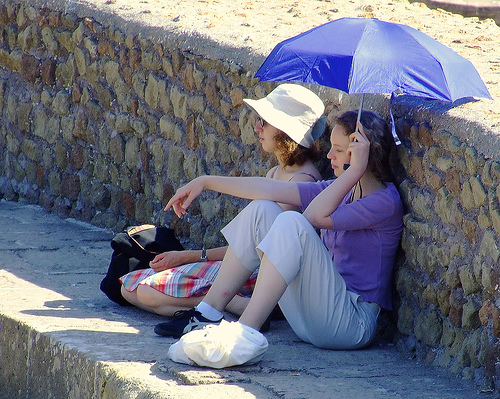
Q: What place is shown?
A: It is a sidewalk.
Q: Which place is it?
A: It is a sidewalk.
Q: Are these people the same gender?
A: Yes, all the people are female.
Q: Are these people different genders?
A: No, all the people are female.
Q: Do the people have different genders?
A: No, all the people are female.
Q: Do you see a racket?
A: No, there are no rackets.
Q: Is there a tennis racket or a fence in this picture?
A: No, there are no rackets or fences.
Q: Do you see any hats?
A: Yes, there is a hat.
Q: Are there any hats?
A: Yes, there is a hat.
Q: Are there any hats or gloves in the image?
A: Yes, there is a hat.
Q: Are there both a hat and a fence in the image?
A: No, there is a hat but no fences.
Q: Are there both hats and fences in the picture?
A: No, there is a hat but no fences.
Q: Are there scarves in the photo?
A: No, there are no scarves.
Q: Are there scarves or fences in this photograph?
A: No, there are no scarves or fences.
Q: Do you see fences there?
A: No, there are no fences.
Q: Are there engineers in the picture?
A: No, there are no engineers.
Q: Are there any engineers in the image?
A: No, there are no engineers.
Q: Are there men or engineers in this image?
A: No, there are no engineers or men.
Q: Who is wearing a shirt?
A: The girl is wearing a shirt.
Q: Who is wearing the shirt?
A: The girl is wearing a shirt.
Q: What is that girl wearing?
A: The girl is wearing a shirt.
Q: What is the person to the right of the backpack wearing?
A: The girl is wearing a shirt.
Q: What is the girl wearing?
A: The girl is wearing a shirt.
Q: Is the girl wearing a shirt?
A: Yes, the girl is wearing a shirt.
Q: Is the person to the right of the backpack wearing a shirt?
A: Yes, the girl is wearing a shirt.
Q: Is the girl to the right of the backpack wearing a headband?
A: No, the girl is wearing a shirt.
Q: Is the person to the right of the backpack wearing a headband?
A: No, the girl is wearing a shirt.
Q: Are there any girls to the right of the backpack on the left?
A: Yes, there is a girl to the right of the backpack.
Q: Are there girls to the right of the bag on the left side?
A: Yes, there is a girl to the right of the backpack.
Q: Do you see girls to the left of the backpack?
A: No, the girl is to the right of the backpack.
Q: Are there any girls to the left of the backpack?
A: No, the girl is to the right of the backpack.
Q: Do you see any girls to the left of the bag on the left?
A: No, the girl is to the right of the backpack.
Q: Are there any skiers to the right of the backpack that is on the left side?
A: No, there is a girl to the right of the backpack.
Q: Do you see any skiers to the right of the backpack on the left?
A: No, there is a girl to the right of the backpack.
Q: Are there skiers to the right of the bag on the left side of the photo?
A: No, there is a girl to the right of the backpack.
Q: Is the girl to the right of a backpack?
A: Yes, the girl is to the right of a backpack.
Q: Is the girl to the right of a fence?
A: No, the girl is to the right of a backpack.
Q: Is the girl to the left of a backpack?
A: No, the girl is to the right of a backpack.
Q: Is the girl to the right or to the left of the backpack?
A: The girl is to the right of the backpack.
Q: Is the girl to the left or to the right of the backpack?
A: The girl is to the right of the backpack.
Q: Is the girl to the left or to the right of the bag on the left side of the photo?
A: The girl is to the right of the backpack.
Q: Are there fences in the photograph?
A: No, there are no fences.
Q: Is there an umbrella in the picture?
A: Yes, there is an umbrella.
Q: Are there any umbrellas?
A: Yes, there is an umbrella.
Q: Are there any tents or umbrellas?
A: Yes, there is an umbrella.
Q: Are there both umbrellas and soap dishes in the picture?
A: No, there is an umbrella but no soap dishes.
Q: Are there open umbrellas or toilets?
A: Yes, there is an open umbrella.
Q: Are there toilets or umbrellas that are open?
A: Yes, the umbrella is open.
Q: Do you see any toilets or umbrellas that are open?
A: Yes, the umbrella is open.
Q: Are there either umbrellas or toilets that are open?
A: Yes, the umbrella is open.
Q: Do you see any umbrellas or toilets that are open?
A: Yes, the umbrella is open.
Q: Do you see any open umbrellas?
A: Yes, there is an open umbrella.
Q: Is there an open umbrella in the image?
A: Yes, there is an open umbrella.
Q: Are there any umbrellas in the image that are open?
A: Yes, there is an umbrella that is open.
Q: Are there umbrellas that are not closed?
A: Yes, there is a open umbrella.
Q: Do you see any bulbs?
A: No, there are no bulbs.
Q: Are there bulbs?
A: No, there are no bulbs.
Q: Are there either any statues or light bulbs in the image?
A: No, there are no light bulbs or statues.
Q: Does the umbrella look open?
A: Yes, the umbrella is open.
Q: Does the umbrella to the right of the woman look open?
A: Yes, the umbrella is open.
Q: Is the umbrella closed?
A: No, the umbrella is open.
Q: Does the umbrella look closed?
A: No, the umbrella is open.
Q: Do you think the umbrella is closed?
A: No, the umbrella is open.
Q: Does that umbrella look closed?
A: No, the umbrella is open.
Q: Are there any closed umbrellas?
A: No, there is an umbrella but it is open.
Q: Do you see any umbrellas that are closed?
A: No, there is an umbrella but it is open.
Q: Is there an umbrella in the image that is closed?
A: No, there is an umbrella but it is open.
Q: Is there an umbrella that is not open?
A: No, there is an umbrella but it is open.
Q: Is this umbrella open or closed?
A: The umbrella is open.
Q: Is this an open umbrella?
A: Yes, this is an open umbrella.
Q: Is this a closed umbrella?
A: No, this is an open umbrella.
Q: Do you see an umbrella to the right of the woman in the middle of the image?
A: Yes, there is an umbrella to the right of the woman.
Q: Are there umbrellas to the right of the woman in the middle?
A: Yes, there is an umbrella to the right of the woman.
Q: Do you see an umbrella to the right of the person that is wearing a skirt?
A: Yes, there is an umbrella to the right of the woman.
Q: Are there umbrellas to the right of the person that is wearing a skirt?
A: Yes, there is an umbrella to the right of the woman.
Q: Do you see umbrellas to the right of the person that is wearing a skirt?
A: Yes, there is an umbrella to the right of the woman.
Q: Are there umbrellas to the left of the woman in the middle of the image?
A: No, the umbrella is to the right of the woman.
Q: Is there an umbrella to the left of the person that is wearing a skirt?
A: No, the umbrella is to the right of the woman.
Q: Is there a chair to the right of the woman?
A: No, there is an umbrella to the right of the woman.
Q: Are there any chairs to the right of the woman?
A: No, there is an umbrella to the right of the woman.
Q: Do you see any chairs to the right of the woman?
A: No, there is an umbrella to the right of the woman.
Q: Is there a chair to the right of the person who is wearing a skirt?
A: No, there is an umbrella to the right of the woman.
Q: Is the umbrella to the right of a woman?
A: Yes, the umbrella is to the right of a woman.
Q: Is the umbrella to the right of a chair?
A: No, the umbrella is to the right of a woman.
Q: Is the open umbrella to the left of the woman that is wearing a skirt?
A: No, the umbrella is to the right of the woman.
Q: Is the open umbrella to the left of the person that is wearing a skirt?
A: No, the umbrella is to the right of the woman.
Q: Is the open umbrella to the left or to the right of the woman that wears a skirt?
A: The umbrella is to the right of the woman.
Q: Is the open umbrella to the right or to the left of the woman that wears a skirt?
A: The umbrella is to the right of the woman.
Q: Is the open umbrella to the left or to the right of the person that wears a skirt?
A: The umbrella is to the right of the woman.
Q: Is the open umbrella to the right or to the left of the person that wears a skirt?
A: The umbrella is to the right of the woman.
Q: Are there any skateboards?
A: No, there are no skateboards.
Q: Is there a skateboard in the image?
A: No, there are no skateboards.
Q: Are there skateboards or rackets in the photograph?
A: No, there are no skateboards or rackets.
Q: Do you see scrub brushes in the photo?
A: No, there are no scrub brushes.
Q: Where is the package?
A: The package is on the sidewalk.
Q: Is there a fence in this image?
A: No, there are no fences.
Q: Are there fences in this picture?
A: No, there are no fences.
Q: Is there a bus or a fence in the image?
A: No, there are no fences or buses.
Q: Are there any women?
A: Yes, there is a woman.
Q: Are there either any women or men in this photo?
A: Yes, there is a woman.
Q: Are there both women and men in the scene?
A: No, there is a woman but no men.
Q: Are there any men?
A: No, there are no men.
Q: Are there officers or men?
A: No, there are no men or officers.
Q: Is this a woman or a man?
A: This is a woman.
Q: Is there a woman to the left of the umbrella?
A: Yes, there is a woman to the left of the umbrella.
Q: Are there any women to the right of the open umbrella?
A: No, the woman is to the left of the umbrella.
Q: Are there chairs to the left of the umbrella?
A: No, there is a woman to the left of the umbrella.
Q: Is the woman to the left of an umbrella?
A: Yes, the woman is to the left of an umbrella.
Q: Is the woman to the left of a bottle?
A: No, the woman is to the left of an umbrella.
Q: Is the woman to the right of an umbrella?
A: No, the woman is to the left of an umbrella.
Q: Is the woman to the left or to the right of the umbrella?
A: The woman is to the left of the umbrella.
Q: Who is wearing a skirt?
A: The woman is wearing a skirt.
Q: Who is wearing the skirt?
A: The woman is wearing a skirt.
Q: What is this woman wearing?
A: The woman is wearing a skirt.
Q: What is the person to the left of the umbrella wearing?
A: The woman is wearing a skirt.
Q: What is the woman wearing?
A: The woman is wearing a skirt.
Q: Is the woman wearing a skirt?
A: Yes, the woman is wearing a skirt.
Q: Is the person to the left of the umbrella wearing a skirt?
A: Yes, the woman is wearing a skirt.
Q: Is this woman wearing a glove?
A: No, the woman is wearing a skirt.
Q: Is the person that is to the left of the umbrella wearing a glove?
A: No, the woman is wearing a skirt.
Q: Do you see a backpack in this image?
A: Yes, there is a backpack.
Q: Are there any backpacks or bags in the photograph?
A: Yes, there is a backpack.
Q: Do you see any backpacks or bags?
A: Yes, there is a backpack.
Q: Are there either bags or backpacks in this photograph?
A: Yes, there is a backpack.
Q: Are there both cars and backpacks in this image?
A: No, there is a backpack but no cars.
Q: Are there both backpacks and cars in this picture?
A: No, there is a backpack but no cars.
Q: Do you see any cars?
A: No, there are no cars.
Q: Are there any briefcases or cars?
A: No, there are no cars or briefcases.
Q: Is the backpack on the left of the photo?
A: Yes, the backpack is on the left of the image.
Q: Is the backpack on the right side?
A: No, the backpack is on the left of the image.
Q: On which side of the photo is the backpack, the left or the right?
A: The backpack is on the left of the image.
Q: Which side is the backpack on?
A: The backpack is on the left of the image.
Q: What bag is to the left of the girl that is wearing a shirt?
A: The bag is a backpack.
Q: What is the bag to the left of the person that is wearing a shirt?
A: The bag is a backpack.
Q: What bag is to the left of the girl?
A: The bag is a backpack.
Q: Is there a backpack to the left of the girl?
A: Yes, there is a backpack to the left of the girl.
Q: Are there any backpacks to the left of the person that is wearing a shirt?
A: Yes, there is a backpack to the left of the girl.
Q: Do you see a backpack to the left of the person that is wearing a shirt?
A: Yes, there is a backpack to the left of the girl.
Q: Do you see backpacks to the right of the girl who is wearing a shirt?
A: No, the backpack is to the left of the girl.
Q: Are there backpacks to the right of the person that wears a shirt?
A: No, the backpack is to the left of the girl.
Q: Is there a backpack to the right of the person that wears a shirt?
A: No, the backpack is to the left of the girl.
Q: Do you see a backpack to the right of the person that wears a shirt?
A: No, the backpack is to the left of the girl.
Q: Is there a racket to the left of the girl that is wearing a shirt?
A: No, there is a backpack to the left of the girl.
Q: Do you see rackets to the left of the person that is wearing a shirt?
A: No, there is a backpack to the left of the girl.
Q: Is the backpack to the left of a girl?
A: Yes, the backpack is to the left of a girl.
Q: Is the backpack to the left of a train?
A: No, the backpack is to the left of a girl.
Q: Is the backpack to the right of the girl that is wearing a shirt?
A: No, the backpack is to the left of the girl.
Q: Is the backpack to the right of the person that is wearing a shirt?
A: No, the backpack is to the left of the girl.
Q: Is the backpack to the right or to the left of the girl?
A: The backpack is to the left of the girl.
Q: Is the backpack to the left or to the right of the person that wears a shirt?
A: The backpack is to the left of the girl.